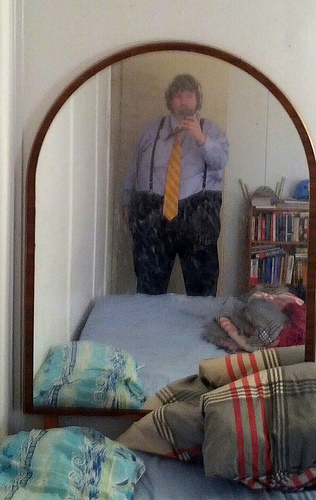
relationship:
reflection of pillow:
[32, 342, 147, 410] [2, 424, 146, 498]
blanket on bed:
[113, 344, 315, 498] [7, 420, 313, 498]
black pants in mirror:
[129, 189, 222, 295] [22, 42, 315, 413]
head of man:
[160, 69, 201, 116] [123, 72, 229, 295]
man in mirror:
[123, 72, 229, 295] [22, 42, 315, 413]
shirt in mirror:
[129, 112, 237, 207] [22, 42, 315, 413]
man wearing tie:
[123, 72, 229, 295] [161, 123, 183, 221]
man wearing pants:
[123, 72, 229, 295] [129, 203, 217, 273]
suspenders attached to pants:
[144, 116, 210, 196] [126, 189, 221, 298]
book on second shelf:
[250, 257, 259, 284] [251, 243, 315, 289]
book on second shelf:
[264, 256, 270, 282] [251, 243, 315, 289]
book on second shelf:
[285, 254, 294, 286] [251, 243, 315, 289]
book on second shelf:
[255, 247, 285, 259] [251, 243, 315, 289]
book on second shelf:
[294, 260, 303, 284] [251, 243, 315, 289]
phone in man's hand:
[176, 112, 213, 134] [178, 115, 201, 133]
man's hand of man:
[179, 115, 201, 140] [123, 72, 229, 295]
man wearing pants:
[105, 75, 281, 223] [123, 191, 222, 286]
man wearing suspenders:
[123, 72, 229, 295] [148, 115, 208, 197]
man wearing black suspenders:
[123, 72, 229, 295] [151, 120, 215, 194]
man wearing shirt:
[123, 72, 229, 295] [138, 117, 228, 206]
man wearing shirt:
[123, 72, 229, 295] [120, 111, 229, 210]